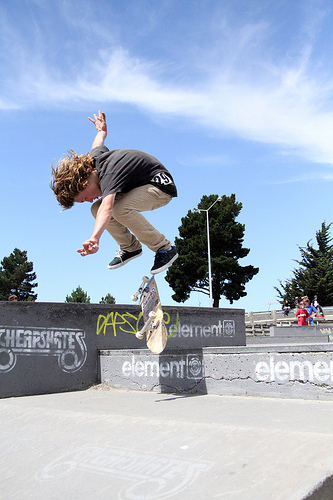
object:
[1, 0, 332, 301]
air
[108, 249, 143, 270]
shoes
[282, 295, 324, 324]
people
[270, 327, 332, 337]
sidewalk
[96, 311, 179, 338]
graffiti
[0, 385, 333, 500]
ground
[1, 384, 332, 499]
surface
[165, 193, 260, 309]
pine tree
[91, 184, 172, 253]
pants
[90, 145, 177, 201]
black shirt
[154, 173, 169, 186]
number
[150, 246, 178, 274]
shoe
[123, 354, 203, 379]
logo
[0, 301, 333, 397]
wall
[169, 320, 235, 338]
logo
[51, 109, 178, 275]
boy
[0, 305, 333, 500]
skate park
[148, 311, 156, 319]
wheels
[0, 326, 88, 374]
logo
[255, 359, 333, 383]
logo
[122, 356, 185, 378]
word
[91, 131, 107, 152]
arm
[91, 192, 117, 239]
arm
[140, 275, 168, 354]
flying skateboard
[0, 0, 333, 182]
cloud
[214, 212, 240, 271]
leaves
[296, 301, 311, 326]
boy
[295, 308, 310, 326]
shirt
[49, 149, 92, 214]
hair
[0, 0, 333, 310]
sky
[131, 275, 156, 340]
bottom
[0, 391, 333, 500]
skate ramp